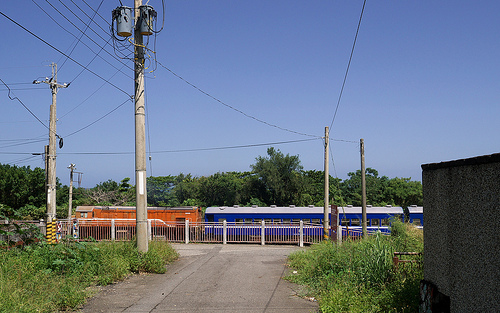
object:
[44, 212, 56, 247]
poles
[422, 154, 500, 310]
concrete building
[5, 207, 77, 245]
wall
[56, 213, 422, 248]
fence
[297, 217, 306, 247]
post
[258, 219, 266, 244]
post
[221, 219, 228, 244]
post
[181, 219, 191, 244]
post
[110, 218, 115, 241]
post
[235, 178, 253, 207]
clock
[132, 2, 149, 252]
pole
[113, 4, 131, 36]
transformer bucket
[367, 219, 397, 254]
clock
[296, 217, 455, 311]
green brush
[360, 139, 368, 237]
post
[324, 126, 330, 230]
post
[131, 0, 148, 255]
post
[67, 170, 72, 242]
post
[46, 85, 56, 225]
post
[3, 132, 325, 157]
power line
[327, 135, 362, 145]
power line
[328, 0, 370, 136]
power line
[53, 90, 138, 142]
power line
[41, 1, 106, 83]
power line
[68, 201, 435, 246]
train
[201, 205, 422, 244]
cars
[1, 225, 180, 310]
plants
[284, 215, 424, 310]
plants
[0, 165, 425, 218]
plants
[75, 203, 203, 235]
passenger train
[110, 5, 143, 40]
buckets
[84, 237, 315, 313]
road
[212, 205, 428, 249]
wall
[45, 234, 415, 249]
tracks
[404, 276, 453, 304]
clock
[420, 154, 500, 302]
wall